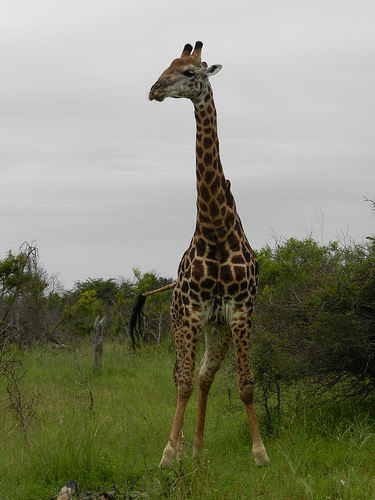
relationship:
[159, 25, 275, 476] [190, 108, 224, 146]
giraffe has neck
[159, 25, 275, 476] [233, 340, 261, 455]
giraffe has leg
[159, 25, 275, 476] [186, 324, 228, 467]
giraffe has leg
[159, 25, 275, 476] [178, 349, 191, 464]
giraffe has leg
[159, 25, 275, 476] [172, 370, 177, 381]
giraffe has leg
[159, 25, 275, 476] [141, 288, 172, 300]
giraffe has tail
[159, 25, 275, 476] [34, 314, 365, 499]
giraffe standing in meadow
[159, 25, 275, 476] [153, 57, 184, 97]
giraffe has head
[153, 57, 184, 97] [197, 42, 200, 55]
head has horn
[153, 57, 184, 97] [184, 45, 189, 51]
head has horn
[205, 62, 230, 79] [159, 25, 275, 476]
ear on giraffe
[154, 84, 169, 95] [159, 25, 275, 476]
muzzle on giraffe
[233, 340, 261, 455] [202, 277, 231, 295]
leg in front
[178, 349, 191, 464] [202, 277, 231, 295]
leg in front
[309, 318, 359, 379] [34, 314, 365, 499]
bush in meadow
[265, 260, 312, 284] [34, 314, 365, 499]
bush in meadow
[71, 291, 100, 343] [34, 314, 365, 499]
bush in meadow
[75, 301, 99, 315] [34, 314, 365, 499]
bush in meadow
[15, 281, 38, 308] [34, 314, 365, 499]
bush in meadow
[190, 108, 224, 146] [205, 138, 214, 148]
neck has spot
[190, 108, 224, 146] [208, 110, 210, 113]
neck has spot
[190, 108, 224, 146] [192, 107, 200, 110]
neck has spot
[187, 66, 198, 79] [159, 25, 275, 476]
eye of giraffe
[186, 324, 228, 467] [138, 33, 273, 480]
leg of giraffe